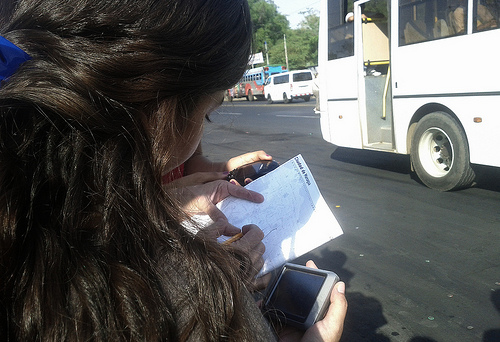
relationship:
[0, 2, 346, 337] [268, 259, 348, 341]
woman has hand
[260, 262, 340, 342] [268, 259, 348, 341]
device in hand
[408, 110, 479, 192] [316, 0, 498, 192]
tire on wheel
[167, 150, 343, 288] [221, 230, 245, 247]
paper being written on with pencil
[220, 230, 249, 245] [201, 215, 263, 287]
pencil in hand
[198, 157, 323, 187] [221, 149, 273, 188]
phone in left hand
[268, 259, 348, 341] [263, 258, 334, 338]
hand holding gps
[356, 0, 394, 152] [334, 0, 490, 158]
door on side of bus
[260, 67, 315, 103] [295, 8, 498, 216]
van driving away from bus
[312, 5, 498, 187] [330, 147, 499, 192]
bus has shadow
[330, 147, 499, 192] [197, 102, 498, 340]
shadow on pavement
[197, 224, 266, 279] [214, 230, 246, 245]
hand holding pencil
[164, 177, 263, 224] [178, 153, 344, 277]
hand holding paper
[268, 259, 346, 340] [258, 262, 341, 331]
hand holding device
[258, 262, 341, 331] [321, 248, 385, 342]
device with shadow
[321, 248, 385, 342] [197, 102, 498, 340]
shadow on pavement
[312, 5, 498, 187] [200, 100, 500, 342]
bus on pavement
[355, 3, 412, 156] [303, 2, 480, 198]
door of bus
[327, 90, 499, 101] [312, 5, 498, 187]
stripe on side of bus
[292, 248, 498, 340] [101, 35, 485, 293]
shadow on street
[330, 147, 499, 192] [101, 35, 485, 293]
shadow on street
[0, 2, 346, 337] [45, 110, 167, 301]
woman with hair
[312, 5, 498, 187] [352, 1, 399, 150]
bus has door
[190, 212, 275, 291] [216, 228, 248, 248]
hand writing with pencil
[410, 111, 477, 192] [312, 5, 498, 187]
tire on bus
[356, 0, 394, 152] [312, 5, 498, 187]
door on bus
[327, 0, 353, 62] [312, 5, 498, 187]
window on bus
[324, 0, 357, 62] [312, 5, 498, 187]
window on bus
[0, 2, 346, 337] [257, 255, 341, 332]
woman holding device